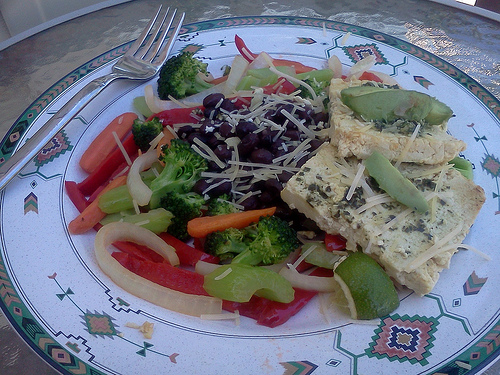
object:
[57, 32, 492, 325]
meal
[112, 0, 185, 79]
head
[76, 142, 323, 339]
peppers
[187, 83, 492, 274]
cheese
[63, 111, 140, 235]
carrots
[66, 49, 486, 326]
salad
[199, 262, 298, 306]
celery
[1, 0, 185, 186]
fork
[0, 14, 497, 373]
plate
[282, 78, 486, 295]
tofu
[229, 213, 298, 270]
broccoli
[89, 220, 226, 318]
onion slice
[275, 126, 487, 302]
tofu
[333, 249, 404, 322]
lime piece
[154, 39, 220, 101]
brocolli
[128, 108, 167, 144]
brocolli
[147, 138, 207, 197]
brocolli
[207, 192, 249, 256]
brocolli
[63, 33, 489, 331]
vegetable meal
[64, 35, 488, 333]
vegatables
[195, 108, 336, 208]
salad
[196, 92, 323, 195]
beans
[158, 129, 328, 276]
salad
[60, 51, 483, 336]
dish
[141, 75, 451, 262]
salad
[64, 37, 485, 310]
food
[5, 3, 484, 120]
table